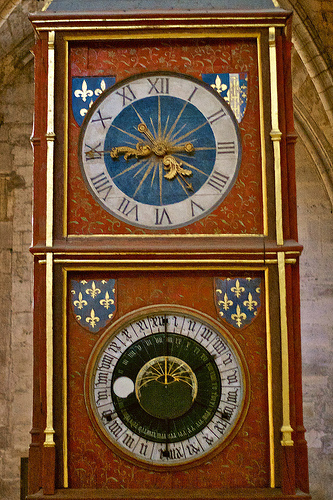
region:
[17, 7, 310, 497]
large clock on a building featuring a moon dial clock below it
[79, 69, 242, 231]
round face of the clock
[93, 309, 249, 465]
round face of the moon dial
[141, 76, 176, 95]
Roman numeral 12 on the clock face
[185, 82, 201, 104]
Roman numeral 1 on the clock face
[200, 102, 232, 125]
Roman numeral 2 on the clock face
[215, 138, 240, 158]
Roman numeral 3 on the clock face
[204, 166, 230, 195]
Roman numeral 4 on the clock face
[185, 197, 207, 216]
Roman numeral 5 on the clock face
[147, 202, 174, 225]
Roman numeral 6 on the clock face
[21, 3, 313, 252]
A clock is on the tower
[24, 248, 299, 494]
an astronomical clock is on the bottom portion of the tower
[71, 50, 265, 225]
the time clock displays roman numerals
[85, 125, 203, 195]
the time shown is 3:45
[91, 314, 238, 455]
the outer ring is the hour of the day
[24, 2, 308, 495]
the tower is made of wood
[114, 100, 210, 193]
the background is blue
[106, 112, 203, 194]
the dials on the clock are gold in color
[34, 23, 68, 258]
gold trim is on the wood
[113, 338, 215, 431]
the green ring indicating the age of the moon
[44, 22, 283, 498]
two clocks on surface of wooden tower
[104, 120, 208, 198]
gold hands on clock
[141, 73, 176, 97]
roman numeral on clock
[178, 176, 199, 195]
arrow on clock hand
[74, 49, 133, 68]
floral pattern on back of clock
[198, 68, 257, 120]
blue and gold arrow shaped image on clock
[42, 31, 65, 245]
gold design on edge of clock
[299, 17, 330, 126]
brown marks on edge of stone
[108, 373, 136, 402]
white circle on front of clock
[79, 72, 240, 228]
Round clock face on wall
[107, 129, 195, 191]
Ornate golden hands on clock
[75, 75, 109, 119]
Decorative blue crest beside clock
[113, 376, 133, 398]
White circle on face of clock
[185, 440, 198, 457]
Roman numeral on clock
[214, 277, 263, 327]
Blue crest on wood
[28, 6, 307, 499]
Wooden case with two clocks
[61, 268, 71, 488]
Gold painted trim on wood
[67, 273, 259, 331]
Two blue crests on wood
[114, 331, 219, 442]
Black circle in center of clock face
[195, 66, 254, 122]
a shield on a clock.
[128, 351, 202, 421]
a picture in the center of a clock.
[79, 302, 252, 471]
a large roman numeral clock.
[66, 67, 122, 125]
a coat of arms on a clock.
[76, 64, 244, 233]
a large roman numeral clock face.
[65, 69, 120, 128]
a colorful shield.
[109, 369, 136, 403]
a moon on a clock.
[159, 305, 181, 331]
a numeral on a clock.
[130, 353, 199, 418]
the center of a clock.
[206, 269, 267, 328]
a large blue shield.